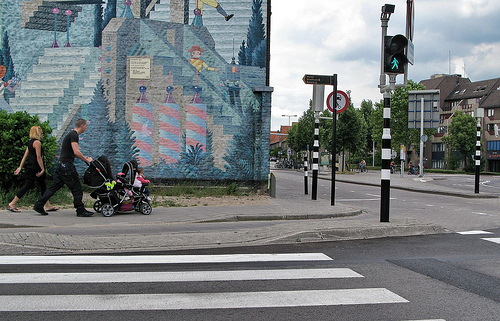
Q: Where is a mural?
A: On the wall.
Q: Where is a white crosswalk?
A: In the street.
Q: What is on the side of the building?
A: A mural.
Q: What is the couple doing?
A: Walking on the sidewalk.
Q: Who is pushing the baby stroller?
A: A man.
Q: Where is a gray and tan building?
A: On the far right.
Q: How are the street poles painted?
A: Black and white.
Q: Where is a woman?
A: Walking with a man.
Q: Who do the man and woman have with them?
A: Baby in a stroller.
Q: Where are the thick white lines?
A: On the road.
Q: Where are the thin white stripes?
A: On the black poles.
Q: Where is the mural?
A: On the building.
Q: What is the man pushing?
A: A baby stroller.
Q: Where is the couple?
A: By the building.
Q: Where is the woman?
A: By the man.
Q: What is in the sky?
A: Clouds.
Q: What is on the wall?
A: A mural.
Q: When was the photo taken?
A: Daytime.